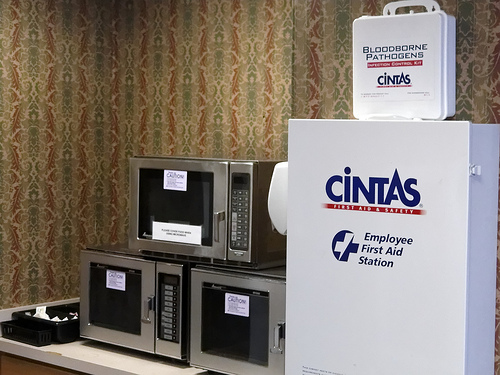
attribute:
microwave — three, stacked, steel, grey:
[71, 142, 286, 312]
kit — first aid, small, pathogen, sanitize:
[343, 5, 466, 122]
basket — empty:
[26, 273, 123, 349]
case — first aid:
[258, 108, 458, 372]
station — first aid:
[363, 159, 469, 316]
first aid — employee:
[284, 120, 440, 295]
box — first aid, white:
[323, 212, 410, 291]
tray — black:
[4, 292, 69, 352]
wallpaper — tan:
[46, 55, 107, 160]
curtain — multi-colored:
[135, 42, 249, 107]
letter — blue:
[287, 161, 425, 210]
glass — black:
[162, 184, 216, 211]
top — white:
[65, 345, 102, 370]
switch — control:
[227, 183, 254, 235]